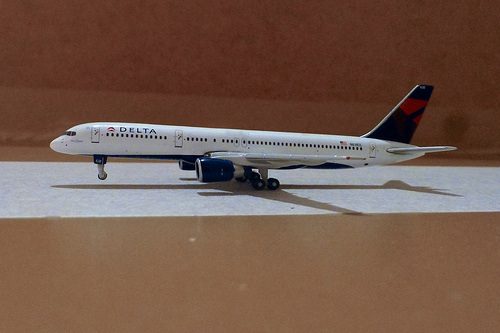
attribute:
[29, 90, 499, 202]
airplanes — small, model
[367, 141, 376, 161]
exit door — rear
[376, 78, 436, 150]
tail fin — large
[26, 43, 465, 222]
airplane — white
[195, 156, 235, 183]
engine — large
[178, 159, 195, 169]
engine — large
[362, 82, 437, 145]
tail — blue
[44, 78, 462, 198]
plane — white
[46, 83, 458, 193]
airplane — delta, model